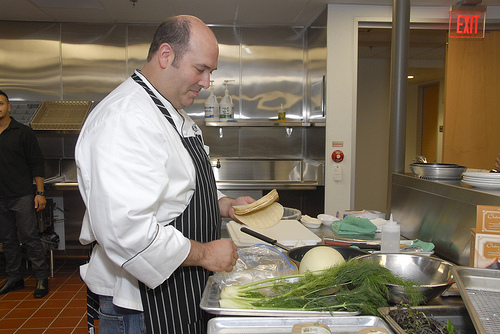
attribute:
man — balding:
[73, 15, 284, 332]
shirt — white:
[72, 69, 221, 312]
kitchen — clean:
[0, 3, 498, 331]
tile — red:
[41, 299, 96, 333]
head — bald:
[143, 11, 219, 110]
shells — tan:
[234, 186, 284, 230]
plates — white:
[461, 163, 499, 189]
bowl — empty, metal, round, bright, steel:
[347, 251, 459, 307]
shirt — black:
[2, 117, 47, 202]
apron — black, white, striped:
[131, 71, 221, 333]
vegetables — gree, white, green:
[402, 312, 456, 333]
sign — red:
[449, 9, 489, 41]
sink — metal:
[42, 127, 328, 275]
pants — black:
[0, 194, 52, 279]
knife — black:
[241, 226, 297, 253]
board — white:
[227, 218, 322, 249]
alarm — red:
[330, 140, 348, 181]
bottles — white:
[203, 78, 236, 123]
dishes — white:
[301, 208, 342, 228]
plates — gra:
[410, 160, 467, 181]